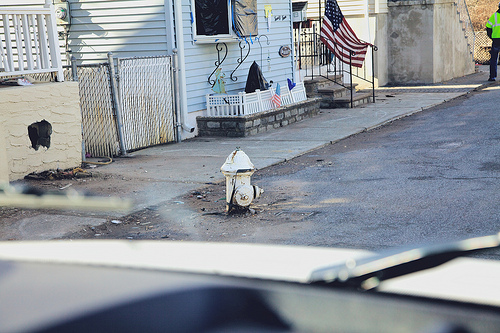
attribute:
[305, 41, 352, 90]
railing — black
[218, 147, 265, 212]
fire hydrant — white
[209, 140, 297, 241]
hydrant — fire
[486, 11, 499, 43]
vest — green, safety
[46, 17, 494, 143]
wall — stone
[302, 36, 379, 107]
railing — wrought iron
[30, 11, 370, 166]
wall — concrete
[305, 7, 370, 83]
american flag — American 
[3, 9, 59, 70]
railing — white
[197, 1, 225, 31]
plastic — black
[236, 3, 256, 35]
plastic — black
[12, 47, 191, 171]
fence — white, grey, chain link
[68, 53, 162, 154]
fence — white